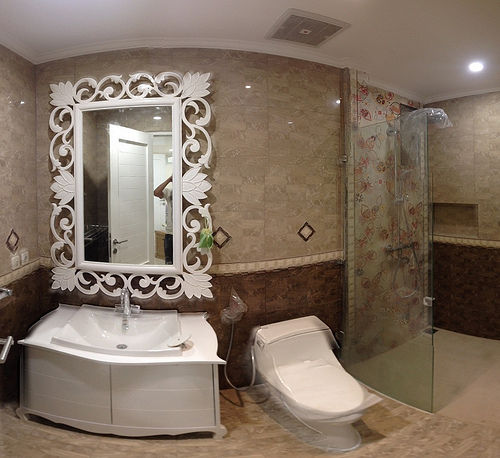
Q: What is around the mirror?
A: Frame.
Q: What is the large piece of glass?
A: Shower door.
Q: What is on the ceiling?
A: Vent.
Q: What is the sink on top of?
A: Cabinet.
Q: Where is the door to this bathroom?
A: Reflected in mirror.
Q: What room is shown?
A: Bathroom.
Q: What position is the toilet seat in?
A: Down.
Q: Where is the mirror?
A: Over the sink.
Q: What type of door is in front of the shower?
A: Glass.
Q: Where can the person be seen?
A: Reflection in the mirror.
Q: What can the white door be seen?
A: Reflection in mirror.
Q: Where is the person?
A: Standing in the doorway.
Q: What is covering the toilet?
A: Plastic.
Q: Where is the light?
A: Ceiling over the shower.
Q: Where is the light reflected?
A: Walls.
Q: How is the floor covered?
A: With brown tile.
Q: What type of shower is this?
A: Shower without a threshold.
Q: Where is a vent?
A: On the ceiling.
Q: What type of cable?
A: Water line.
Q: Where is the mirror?
A: On wall.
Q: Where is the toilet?
A: Next to sink.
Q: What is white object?
A: Toilet.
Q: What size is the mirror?
A: Large.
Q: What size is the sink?
A: Large.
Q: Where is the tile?
A: On wall.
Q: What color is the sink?
A: White.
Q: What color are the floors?
A: Cream.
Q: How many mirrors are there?
A: One.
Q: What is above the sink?
A: The mirror.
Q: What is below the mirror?
A: The sink.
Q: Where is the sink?
A: Below the mirror.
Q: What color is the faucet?
A: Silver.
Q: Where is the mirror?
A: Above the sink.